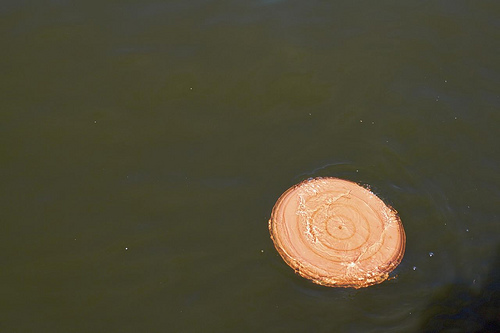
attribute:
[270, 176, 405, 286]
frisbee — red, cracked, round, orange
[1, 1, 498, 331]
water — murky, green, brown, dark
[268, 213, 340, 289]
edge — thick